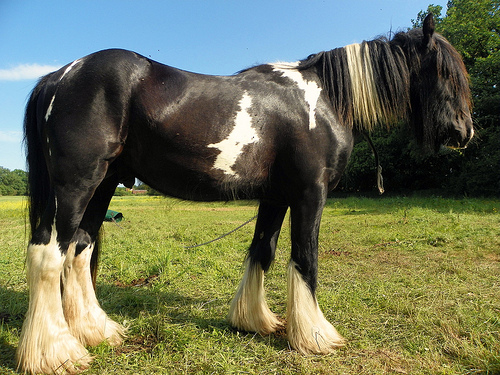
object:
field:
[1, 194, 498, 373]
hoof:
[287, 315, 342, 351]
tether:
[184, 214, 260, 249]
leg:
[285, 155, 349, 357]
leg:
[226, 202, 291, 333]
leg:
[11, 138, 113, 375]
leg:
[61, 162, 126, 349]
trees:
[345, 4, 498, 194]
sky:
[125, 12, 307, 51]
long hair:
[229, 253, 279, 332]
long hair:
[69, 240, 130, 349]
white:
[289, 270, 348, 357]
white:
[15, 248, 84, 371]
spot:
[206, 91, 260, 179]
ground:
[0, 190, 499, 374]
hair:
[320, 38, 411, 132]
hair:
[21, 281, 66, 373]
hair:
[427, 33, 471, 108]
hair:
[289, 286, 344, 356]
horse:
[19, 11, 479, 375]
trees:
[0, 170, 33, 199]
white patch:
[272, 62, 323, 128]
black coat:
[75, 56, 284, 191]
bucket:
[105, 209, 121, 222]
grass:
[0, 190, 498, 374]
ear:
[420, 12, 436, 47]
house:
[125, 188, 146, 195]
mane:
[312, 38, 419, 134]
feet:
[16, 314, 87, 372]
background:
[0, 0, 498, 372]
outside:
[0, 0, 499, 375]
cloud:
[8, 49, 85, 112]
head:
[406, 11, 476, 156]